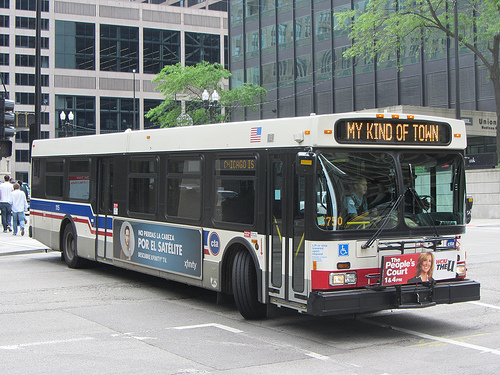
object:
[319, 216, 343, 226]
number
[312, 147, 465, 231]
windshield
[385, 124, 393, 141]
letter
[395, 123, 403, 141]
letter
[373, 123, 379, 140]
letter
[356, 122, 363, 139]
letter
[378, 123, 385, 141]
letter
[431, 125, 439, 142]
letter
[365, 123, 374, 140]
letter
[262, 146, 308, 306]
doors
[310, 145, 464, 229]
window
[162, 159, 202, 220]
window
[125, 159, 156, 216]
window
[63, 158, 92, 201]
window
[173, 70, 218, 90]
green leaves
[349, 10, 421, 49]
green leaves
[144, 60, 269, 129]
tree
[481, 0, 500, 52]
branches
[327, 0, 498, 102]
tree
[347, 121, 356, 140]
letter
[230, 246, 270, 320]
tire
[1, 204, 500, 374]
road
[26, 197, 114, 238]
stripe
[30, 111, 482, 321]
bus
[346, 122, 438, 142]
orange letter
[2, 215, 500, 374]
street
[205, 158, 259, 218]
window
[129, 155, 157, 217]
window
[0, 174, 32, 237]
people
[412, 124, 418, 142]
letter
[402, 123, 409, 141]
letter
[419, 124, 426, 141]
letter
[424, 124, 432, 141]
letter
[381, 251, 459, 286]
banner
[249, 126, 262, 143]
american flag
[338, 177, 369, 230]
driver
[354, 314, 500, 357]
line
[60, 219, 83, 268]
tire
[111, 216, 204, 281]
banner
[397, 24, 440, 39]
branch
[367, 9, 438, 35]
branch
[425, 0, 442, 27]
branch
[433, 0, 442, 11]
branch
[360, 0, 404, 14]
branch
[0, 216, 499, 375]
ground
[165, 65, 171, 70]
leaf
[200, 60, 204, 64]
leaf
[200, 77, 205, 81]
leaf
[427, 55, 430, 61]
leaf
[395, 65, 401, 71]
leaf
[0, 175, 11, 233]
person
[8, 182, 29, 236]
person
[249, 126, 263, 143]
sticker